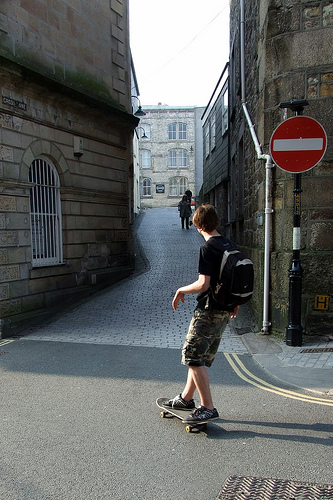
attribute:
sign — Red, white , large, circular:
[268, 114, 328, 172]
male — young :
[214, 238, 258, 311]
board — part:
[178, 404, 185, 411]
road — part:
[4, 207, 331, 491]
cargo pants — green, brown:
[180, 304, 228, 365]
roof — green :
[135, 105, 196, 110]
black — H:
[80, 443, 128, 475]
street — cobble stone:
[9, 204, 329, 498]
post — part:
[285, 173, 306, 351]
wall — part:
[0, 6, 131, 283]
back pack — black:
[209, 243, 255, 311]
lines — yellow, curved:
[224, 351, 322, 406]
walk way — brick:
[20, 204, 253, 351]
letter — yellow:
[312, 293, 322, 308]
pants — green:
[181, 302, 234, 366]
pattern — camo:
[183, 308, 238, 367]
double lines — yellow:
[222, 352, 332, 410]